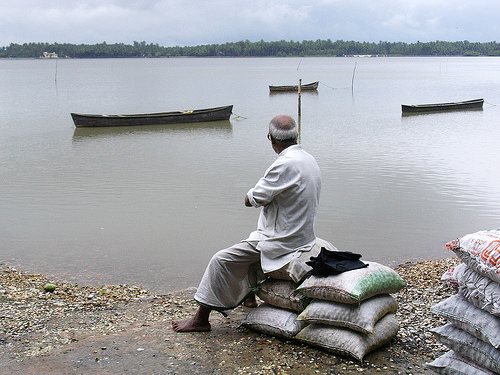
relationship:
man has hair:
[171, 114, 325, 333] [267, 120, 298, 142]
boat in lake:
[70, 102, 237, 130] [1, 57, 499, 287]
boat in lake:
[266, 80, 322, 93] [1, 57, 499, 287]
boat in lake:
[400, 96, 487, 116] [1, 57, 499, 287]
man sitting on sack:
[171, 114, 325, 333] [293, 258, 406, 304]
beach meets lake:
[1, 258, 466, 374] [1, 57, 499, 287]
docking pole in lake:
[298, 77, 303, 119] [1, 57, 499, 287]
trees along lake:
[0, 40, 499, 59] [1, 57, 499, 287]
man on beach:
[171, 114, 325, 333] [1, 258, 466, 374]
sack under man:
[293, 258, 406, 304] [171, 114, 325, 333]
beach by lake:
[1, 258, 466, 374] [1, 57, 499, 287]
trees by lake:
[0, 40, 499, 59] [1, 57, 499, 287]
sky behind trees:
[1, 0, 500, 48] [0, 40, 499, 59]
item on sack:
[304, 245, 370, 280] [293, 258, 406, 304]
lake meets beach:
[1, 57, 499, 287] [1, 258, 466, 374]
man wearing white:
[171, 114, 325, 333] [242, 142, 326, 275]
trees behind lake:
[0, 40, 499, 59] [1, 57, 499, 287]